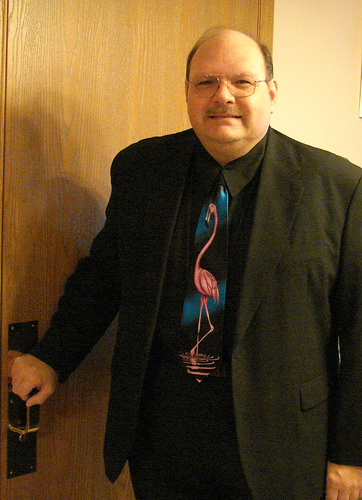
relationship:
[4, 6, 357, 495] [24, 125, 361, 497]
man in suit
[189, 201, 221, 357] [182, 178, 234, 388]
flamingo on tie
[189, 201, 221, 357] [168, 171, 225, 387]
flamingo on necktie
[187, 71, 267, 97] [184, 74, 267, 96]
eyeglasses are metal framed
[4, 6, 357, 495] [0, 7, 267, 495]
man standing in front of door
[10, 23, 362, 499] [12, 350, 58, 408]
man holding hand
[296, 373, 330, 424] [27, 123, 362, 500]
pockets on blazer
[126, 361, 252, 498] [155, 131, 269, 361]
trousers match shirt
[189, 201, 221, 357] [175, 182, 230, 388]
flamingo on tie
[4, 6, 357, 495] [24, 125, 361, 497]
man wearing suit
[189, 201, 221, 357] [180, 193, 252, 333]
flamingo on tie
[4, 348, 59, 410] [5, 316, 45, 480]
hand on door handle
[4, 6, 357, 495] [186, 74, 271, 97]
man has on glasses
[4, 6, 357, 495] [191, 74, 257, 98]
man wearing eyeglasses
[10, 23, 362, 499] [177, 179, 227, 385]
man wearing tie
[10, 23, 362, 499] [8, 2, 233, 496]
man holding door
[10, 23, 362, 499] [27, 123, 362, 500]
man wearing blazer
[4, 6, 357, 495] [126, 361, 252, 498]
man wearing trousers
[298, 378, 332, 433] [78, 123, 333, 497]
pockets on blazer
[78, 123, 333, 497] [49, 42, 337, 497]
blazer on man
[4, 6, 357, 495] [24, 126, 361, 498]
man wearing blazer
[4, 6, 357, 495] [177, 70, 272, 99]
man wearing glasses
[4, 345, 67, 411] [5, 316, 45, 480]
hand on door handle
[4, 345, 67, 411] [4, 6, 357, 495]
hand of man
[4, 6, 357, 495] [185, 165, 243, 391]
man wearing a tie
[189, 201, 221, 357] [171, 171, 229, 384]
flamingo on tie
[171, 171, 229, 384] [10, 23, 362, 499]
tie of man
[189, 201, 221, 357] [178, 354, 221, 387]
flamingo standing in pool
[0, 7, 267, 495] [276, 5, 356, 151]
door next to a white wall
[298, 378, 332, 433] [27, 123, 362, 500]
pockets on blazer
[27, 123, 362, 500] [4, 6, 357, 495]
blazer of man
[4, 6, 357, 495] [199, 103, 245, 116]
man has mustache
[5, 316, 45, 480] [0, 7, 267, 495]
door handle on door